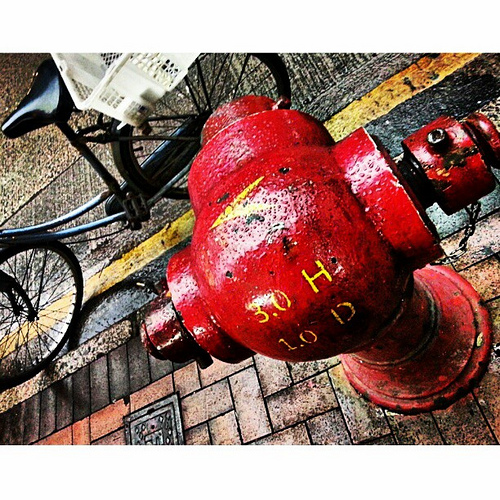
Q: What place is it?
A: It is a road.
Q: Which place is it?
A: It is a road.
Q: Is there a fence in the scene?
A: No, there are no fences.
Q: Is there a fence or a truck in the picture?
A: No, there are no fences or trucks.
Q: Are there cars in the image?
A: No, there are no cars.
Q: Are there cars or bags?
A: No, there are no cars or bags.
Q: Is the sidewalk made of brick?
A: Yes, the sidewalk is made of brick.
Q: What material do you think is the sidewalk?
A: The sidewalk is made of brick.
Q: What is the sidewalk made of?
A: The sidewalk is made of brick.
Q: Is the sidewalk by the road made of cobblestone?
A: No, the sidewalk is made of brick.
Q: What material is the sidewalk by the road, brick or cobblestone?
A: The sidewalk is made of brick.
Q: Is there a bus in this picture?
A: No, there are no buses.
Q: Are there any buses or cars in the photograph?
A: No, there are no buses or cars.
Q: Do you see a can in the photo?
A: No, there are no cans.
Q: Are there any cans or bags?
A: No, there are no cans or bags.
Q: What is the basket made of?
A: The basket is made of plastic.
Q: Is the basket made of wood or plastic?
A: The basket is made of plastic.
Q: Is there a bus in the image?
A: No, there are no buses.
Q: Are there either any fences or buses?
A: No, there are no buses or fences.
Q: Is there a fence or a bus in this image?
A: No, there are no buses or fences.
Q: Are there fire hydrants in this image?
A: Yes, there is a fire hydrant.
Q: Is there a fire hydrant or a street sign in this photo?
A: Yes, there is a fire hydrant.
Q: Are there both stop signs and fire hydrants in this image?
A: No, there is a fire hydrant but no stop signs.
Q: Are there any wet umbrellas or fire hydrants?
A: Yes, there is a wet fire hydrant.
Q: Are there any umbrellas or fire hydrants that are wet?
A: Yes, the fire hydrant is wet.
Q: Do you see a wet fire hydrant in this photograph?
A: Yes, there is a wet fire hydrant.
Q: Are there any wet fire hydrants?
A: Yes, there is a wet fire hydrant.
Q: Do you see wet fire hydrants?
A: Yes, there is a wet fire hydrant.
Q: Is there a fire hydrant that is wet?
A: Yes, there is a fire hydrant that is wet.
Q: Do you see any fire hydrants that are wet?
A: Yes, there is a fire hydrant that is wet.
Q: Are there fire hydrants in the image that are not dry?
A: Yes, there is a wet fire hydrant.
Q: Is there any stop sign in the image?
A: No, there are no stop signs.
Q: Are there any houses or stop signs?
A: No, there are no stop signs or houses.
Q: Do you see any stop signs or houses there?
A: No, there are no stop signs or houses.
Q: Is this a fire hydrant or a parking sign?
A: This is a fire hydrant.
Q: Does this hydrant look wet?
A: Yes, the hydrant is wet.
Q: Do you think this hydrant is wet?
A: Yes, the hydrant is wet.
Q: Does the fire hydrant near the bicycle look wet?
A: Yes, the hydrant is wet.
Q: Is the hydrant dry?
A: No, the hydrant is wet.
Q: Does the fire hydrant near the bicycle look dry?
A: No, the hydrant is wet.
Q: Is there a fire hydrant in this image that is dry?
A: No, there is a fire hydrant but it is wet.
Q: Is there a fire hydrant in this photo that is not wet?
A: No, there is a fire hydrant but it is wet.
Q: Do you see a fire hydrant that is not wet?
A: No, there is a fire hydrant but it is wet.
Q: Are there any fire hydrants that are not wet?
A: No, there is a fire hydrant but it is wet.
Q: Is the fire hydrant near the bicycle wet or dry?
A: The fire hydrant is wet.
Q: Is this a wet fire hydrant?
A: Yes, this is a wet fire hydrant.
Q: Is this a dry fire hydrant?
A: No, this is a wet fire hydrant.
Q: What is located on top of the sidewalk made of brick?
A: The fire hydrant is on top of the sidewalk.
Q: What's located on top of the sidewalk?
A: The fire hydrant is on top of the sidewalk.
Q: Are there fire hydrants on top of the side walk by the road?
A: Yes, there is a fire hydrant on top of the sidewalk.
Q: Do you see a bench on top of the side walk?
A: No, there is a fire hydrant on top of the side walk.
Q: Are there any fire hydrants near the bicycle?
A: Yes, there is a fire hydrant near the bicycle.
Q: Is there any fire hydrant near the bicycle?
A: Yes, there is a fire hydrant near the bicycle.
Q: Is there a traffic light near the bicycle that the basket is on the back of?
A: No, there is a fire hydrant near the bicycle.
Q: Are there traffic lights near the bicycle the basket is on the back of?
A: No, there is a fire hydrant near the bicycle.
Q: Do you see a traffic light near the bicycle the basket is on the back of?
A: No, there is a fire hydrant near the bicycle.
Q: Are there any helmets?
A: No, there are no helmets.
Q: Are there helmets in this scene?
A: No, there are no helmets.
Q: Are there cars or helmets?
A: No, there are no helmets or cars.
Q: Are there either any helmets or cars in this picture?
A: No, there are no helmets or cars.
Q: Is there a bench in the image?
A: No, there are no benches.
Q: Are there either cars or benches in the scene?
A: No, there are no benches or cars.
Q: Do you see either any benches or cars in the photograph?
A: No, there are no benches or cars.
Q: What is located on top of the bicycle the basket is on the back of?
A: The seat is on top of the bicycle.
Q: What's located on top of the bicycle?
A: The seat is on top of the bicycle.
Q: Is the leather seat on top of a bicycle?
A: Yes, the seat is on top of a bicycle.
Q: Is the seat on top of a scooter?
A: No, the seat is on top of a bicycle.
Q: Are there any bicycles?
A: Yes, there is a bicycle.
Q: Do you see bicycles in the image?
A: Yes, there is a bicycle.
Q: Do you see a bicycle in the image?
A: Yes, there is a bicycle.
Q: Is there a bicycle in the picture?
A: Yes, there is a bicycle.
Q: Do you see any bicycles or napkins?
A: Yes, there is a bicycle.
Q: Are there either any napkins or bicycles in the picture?
A: Yes, there is a bicycle.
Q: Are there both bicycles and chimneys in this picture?
A: No, there is a bicycle but no chimneys.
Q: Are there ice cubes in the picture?
A: No, there are no ice cubes.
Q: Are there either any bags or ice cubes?
A: No, there are no ice cubes or bags.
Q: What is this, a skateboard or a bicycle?
A: This is a bicycle.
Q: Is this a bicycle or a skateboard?
A: This is a bicycle.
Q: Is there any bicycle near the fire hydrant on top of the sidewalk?
A: Yes, there is a bicycle near the hydrant.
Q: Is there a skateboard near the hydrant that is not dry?
A: No, there is a bicycle near the hydrant.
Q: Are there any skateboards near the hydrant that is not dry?
A: No, there is a bicycle near the hydrant.